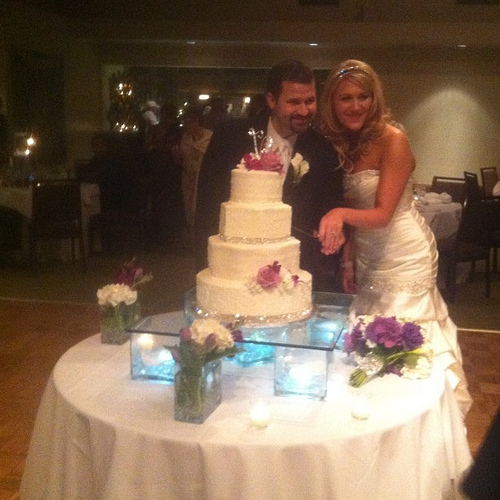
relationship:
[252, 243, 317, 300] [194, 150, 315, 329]
flowers on wedding cake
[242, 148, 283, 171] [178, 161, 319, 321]
flowers on top of cake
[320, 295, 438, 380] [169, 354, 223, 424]
flowers in vase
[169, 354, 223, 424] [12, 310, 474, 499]
vase on table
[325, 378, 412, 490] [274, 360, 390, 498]
candles on side of table